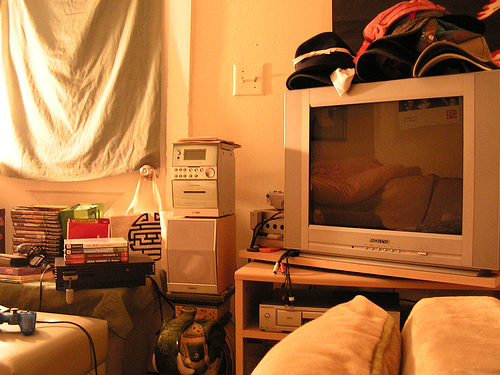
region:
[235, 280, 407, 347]
DVD player in the stand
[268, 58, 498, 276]
a square TV in the room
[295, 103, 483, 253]
reflection of the couch in the TV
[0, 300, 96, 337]
a video game controller and cord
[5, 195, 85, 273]
a stack of video games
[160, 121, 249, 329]
a stereo system and speaker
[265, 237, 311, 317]
cords hanging down from the TV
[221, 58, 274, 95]
two light switches on the wall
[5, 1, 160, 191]
a white sheet on the wall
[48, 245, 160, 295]
a video game system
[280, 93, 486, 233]
the television is off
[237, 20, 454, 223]
the television is off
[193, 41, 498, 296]
the television is off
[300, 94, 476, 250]
reflection of the room on the television screen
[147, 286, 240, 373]
elephant plant stand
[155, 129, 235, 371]
stereo system stacked on plant stand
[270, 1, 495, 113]
pile of hats on top of television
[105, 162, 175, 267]
bag hanging on door knob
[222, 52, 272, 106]
light switch on wall by door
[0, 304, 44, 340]
video game controller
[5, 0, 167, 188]
material hanging on door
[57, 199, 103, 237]
green gift bag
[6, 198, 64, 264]
stack of DVD cases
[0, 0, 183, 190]
white sheet covering a window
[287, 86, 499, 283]
silver box television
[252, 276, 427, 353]
a DVD player under the TV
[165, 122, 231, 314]
a stereo system with speakers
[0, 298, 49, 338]
a video game controller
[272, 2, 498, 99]
a stack of hats on top of a TV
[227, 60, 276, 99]
two light switches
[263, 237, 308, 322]
cords coming out of the TV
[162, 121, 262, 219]
nice silver stereo system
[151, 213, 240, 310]
large silver speaker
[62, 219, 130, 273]
several books lying on dvd player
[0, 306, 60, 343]
hand held game control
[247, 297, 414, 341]
silver dvd player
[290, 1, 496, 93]
several assorted hats and caps on top of tv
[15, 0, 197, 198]
piece of white material covering a window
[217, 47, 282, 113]
white electric light switch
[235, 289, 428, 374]
large white sofa cushion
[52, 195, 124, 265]
red gift bag